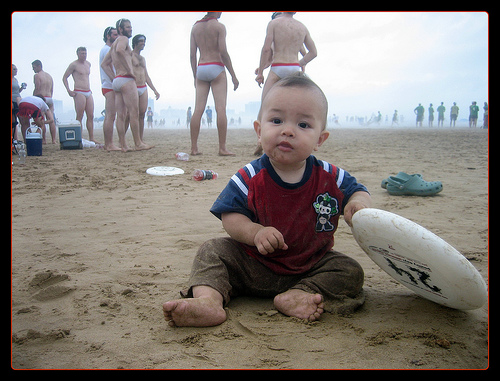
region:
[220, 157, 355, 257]
red and blue shirt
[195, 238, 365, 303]
child has brown pants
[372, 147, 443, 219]
green shoes behind child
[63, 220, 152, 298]
sand is dark brown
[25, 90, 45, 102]
woman has white shirt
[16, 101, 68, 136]
woman has red shorts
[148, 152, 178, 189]
white disc behind child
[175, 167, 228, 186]
bottle with red drink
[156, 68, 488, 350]
A baby with a frisbee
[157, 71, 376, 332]
A baby sitting on the sand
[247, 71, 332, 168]
A baby's head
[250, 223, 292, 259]
A baby's hand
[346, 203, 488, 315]
A white frisbee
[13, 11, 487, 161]
People standing on the beach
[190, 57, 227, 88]
A swimsuit on a man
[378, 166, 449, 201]
A plastic shoe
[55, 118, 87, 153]
An ice cooler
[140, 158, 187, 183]
A white frisbee on the beach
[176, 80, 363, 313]
baby sitting on beach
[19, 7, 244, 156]
people standaing on beach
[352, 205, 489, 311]
frisbee on the beach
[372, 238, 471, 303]
logo on the beach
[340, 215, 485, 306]
the frisbee is round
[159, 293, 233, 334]
foot of the baby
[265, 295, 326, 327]
foot of the baby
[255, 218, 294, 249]
hand of the baby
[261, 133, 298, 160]
mouth of the baby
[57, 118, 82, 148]
green cooler with white lid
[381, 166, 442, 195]
two green plastic shoes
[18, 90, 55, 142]
person in red shorts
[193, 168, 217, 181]
bottle of red liquid tipped over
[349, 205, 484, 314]
frisbee the baby is holding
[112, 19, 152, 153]
guy with a beard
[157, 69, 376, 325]
baby on the beach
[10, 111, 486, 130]
people in ocean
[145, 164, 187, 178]
frisbee on the sand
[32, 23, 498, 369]
a young boy at a beach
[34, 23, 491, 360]
a toddler at a beach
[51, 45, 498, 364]
a young lad at the beach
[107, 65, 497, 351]
a youngster at the beach